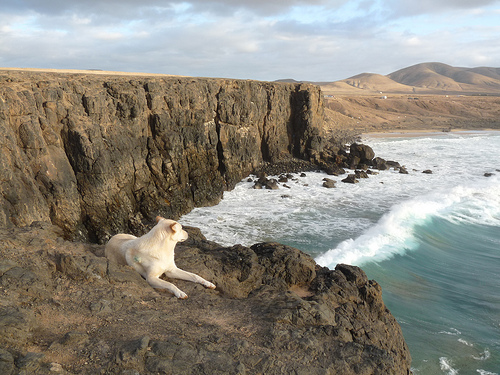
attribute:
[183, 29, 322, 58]
clouds — white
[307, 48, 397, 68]
clouds — white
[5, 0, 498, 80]
sky — blue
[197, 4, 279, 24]
clouds — white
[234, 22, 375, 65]
clouds — white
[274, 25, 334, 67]
clouds — white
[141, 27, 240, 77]
clouds — white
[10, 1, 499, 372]
scene — daytime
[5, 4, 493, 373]
photo — ocean view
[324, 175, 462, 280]
wave — white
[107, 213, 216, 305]
dog — white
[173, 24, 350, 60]
clouds — some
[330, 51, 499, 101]
hills — some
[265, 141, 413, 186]
rocks — some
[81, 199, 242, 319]
dog — lying down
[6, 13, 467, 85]
clouds — white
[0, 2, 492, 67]
sky — blue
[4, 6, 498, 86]
sky — blue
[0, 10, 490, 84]
clouds — white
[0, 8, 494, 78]
sky — blue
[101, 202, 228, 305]
dog — watching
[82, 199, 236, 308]
dog — watching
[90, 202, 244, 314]
dog — watching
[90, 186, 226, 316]
dog — watching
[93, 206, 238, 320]
dog — watching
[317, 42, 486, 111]
dunes — sand, in distance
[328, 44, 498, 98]
dunes — in distance, sand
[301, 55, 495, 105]
dunes — sand, in distance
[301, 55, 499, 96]
dunes — in distance, sand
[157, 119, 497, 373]
ocean — off to right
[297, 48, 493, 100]
hills — some, rolling, in distance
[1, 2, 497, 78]
clouds — white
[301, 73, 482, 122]
land — in region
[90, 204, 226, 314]
dog — golden, yellow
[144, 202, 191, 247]
ears — dog's, set back